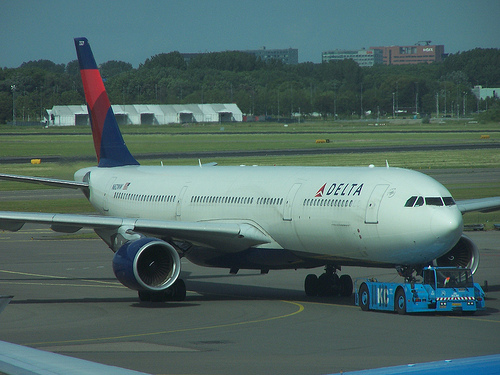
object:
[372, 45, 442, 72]
building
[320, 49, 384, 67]
building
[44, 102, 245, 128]
building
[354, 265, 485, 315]
service vehicle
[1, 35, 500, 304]
airplane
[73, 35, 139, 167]
tail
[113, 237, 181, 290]
turbine engine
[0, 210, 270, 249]
wing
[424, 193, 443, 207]
window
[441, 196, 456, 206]
window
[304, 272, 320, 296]
wheel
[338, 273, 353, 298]
wheel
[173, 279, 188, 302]
wheel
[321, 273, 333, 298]
wheel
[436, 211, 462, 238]
airplane nose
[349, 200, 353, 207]
window